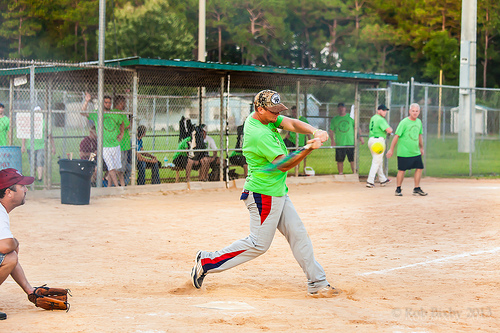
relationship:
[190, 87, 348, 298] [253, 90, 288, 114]
man in baseball cap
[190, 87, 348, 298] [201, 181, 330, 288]
man wearing pants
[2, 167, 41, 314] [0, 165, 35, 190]
man wearing red hat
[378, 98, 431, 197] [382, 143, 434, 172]
man wearing shorts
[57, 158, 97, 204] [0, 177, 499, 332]
trash can on dirt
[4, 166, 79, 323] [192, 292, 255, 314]
catcher crouched behind home plate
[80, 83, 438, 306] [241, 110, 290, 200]
team wearing shirt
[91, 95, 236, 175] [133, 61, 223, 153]
team in dugout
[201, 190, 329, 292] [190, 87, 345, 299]
pants of batter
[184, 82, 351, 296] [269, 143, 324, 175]
player swinging at bat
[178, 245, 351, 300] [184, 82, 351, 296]
cleats of player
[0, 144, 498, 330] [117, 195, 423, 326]
field made of dirt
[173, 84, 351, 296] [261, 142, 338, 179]
man swinging a bat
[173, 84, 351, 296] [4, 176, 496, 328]
man on a baseball field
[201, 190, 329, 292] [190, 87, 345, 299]
pants on batter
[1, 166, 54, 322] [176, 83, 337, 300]
catcher squatting behind batter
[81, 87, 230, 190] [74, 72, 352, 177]
team in dugout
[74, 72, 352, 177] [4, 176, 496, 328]
dugout by baseball field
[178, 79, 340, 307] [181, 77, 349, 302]
man wearing pants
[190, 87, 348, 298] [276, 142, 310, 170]
man holding bat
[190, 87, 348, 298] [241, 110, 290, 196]
man wearing green shirt